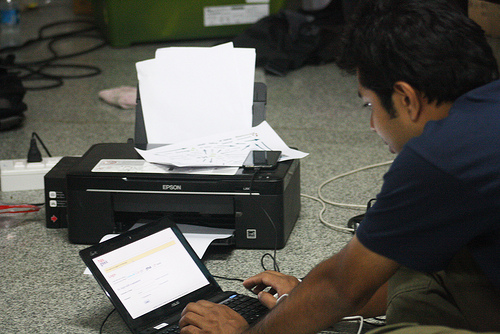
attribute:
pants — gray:
[381, 253, 496, 332]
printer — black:
[37, 126, 302, 271]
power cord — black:
[21, 130, 46, 162]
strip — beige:
[2, 198, 42, 220]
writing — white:
[155, 181, 188, 194]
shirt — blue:
[355, 103, 497, 333]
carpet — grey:
[18, 255, 64, 318]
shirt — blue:
[358, 93, 495, 269]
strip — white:
[0, 153, 80, 192]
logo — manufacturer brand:
[161, 184, 182, 190]